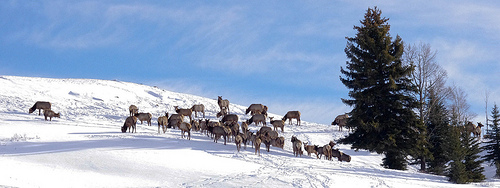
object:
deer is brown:
[281, 110, 302, 126]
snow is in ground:
[0, 75, 500, 187]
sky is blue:
[0, 0, 499, 127]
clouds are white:
[0, 0, 500, 127]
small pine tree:
[441, 119, 473, 184]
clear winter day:
[0, 0, 498, 186]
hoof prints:
[153, 148, 335, 188]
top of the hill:
[0, 75, 157, 96]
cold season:
[0, 0, 499, 188]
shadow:
[0, 130, 381, 160]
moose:
[465, 121, 485, 138]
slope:
[0, 74, 499, 188]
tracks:
[0, 74, 500, 187]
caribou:
[28, 100, 51, 116]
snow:
[0, 75, 500, 187]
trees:
[423, 87, 499, 185]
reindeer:
[120, 116, 138, 134]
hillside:
[0, 74, 499, 188]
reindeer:
[28, 101, 52, 116]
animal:
[177, 121, 192, 141]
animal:
[217, 96, 230, 114]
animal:
[281, 110, 302, 125]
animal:
[28, 101, 52, 116]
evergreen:
[331, 5, 426, 157]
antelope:
[217, 95, 231, 115]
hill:
[0, 73, 499, 188]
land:
[0, 75, 500, 188]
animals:
[302, 140, 351, 162]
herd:
[28, 96, 486, 163]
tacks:
[216, 149, 370, 185]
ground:
[0, 74, 499, 187]